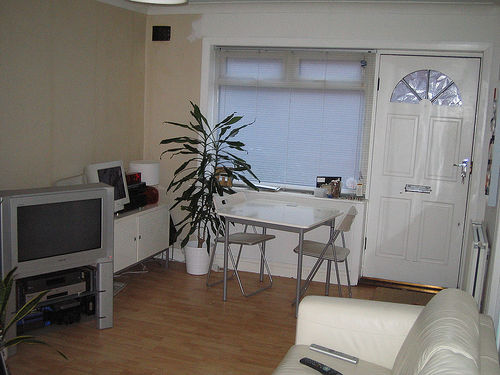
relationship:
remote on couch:
[298, 355, 342, 375] [269, 289, 500, 375]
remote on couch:
[310, 342, 358, 363] [269, 289, 500, 375]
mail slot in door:
[401, 182, 432, 196] [360, 53, 483, 296]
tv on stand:
[1, 182, 114, 281] [1, 260, 118, 344]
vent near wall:
[459, 220, 490, 313] [475, 0, 499, 312]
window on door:
[388, 69, 462, 107] [360, 53, 483, 296]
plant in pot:
[155, 100, 263, 255] [181, 238, 213, 274]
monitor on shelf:
[54, 158, 131, 215] [110, 205, 173, 273]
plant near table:
[155, 100, 263, 255] [215, 196, 345, 320]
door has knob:
[360, 53, 483, 296] [450, 157, 472, 185]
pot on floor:
[181, 238, 213, 274] [1, 259, 448, 372]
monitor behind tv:
[54, 158, 131, 215] [1, 182, 114, 281]